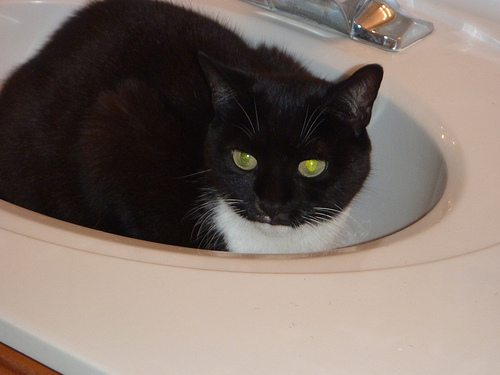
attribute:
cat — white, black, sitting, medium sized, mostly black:
[0, 3, 384, 252]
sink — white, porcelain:
[0, 1, 499, 294]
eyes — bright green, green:
[229, 146, 328, 177]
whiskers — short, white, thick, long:
[187, 189, 248, 251]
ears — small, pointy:
[195, 49, 384, 121]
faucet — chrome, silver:
[251, 0, 436, 50]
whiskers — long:
[230, 93, 263, 139]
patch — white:
[214, 198, 351, 257]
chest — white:
[178, 183, 358, 255]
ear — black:
[326, 63, 385, 122]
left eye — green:
[231, 151, 258, 171]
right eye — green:
[297, 159, 326, 177]